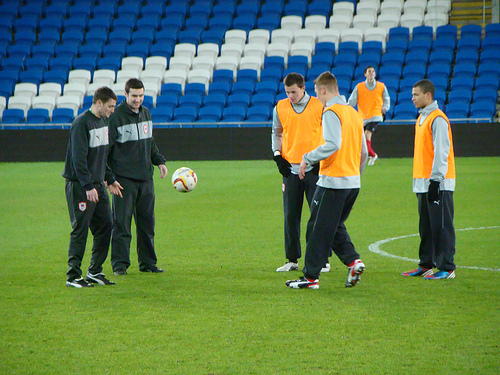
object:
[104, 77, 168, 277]
man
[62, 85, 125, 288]
man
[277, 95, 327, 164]
vest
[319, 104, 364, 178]
vest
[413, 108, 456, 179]
vest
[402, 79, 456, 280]
man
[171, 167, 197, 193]
ball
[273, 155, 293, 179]
glove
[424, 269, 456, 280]
shoe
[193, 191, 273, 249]
grass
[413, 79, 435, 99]
hair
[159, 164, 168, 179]
hand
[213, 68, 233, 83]
seat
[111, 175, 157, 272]
pants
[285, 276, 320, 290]
shoe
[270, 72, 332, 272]
man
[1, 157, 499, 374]
field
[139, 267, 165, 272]
shoe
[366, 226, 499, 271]
line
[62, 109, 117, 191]
shirt